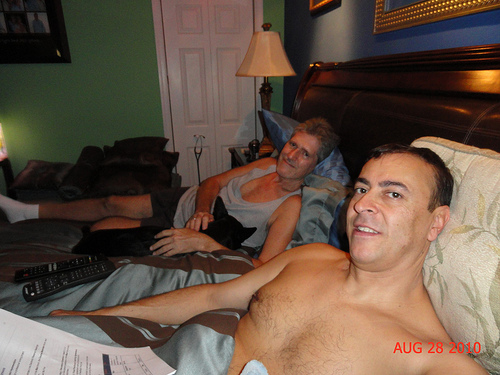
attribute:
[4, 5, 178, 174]
wall — green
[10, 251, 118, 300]
remote — black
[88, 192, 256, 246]
dog — black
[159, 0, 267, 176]
door — white 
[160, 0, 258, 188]
door — white, closed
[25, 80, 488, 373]
people —  two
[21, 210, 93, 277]
socks —  white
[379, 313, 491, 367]
timestamp — red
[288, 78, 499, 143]
bed rest — brown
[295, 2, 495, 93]
wall — blue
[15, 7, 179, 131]
wall — green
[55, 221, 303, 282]
dog — black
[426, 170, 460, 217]
hair — brown